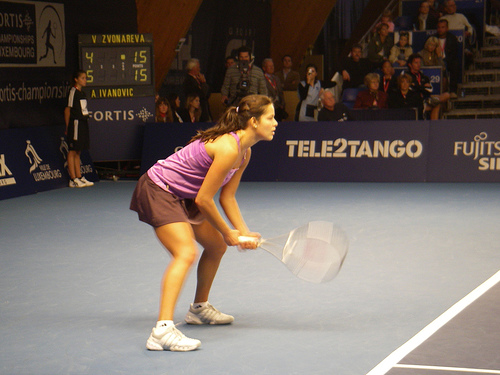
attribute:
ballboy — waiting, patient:
[61, 65, 96, 188]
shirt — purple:
[147, 133, 249, 193]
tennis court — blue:
[0, 185, 495, 370]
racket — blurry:
[254, 209, 365, 290]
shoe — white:
[142, 318, 204, 359]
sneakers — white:
[153, 276, 240, 372]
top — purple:
[143, 131, 248, 197]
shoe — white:
[134, 306, 258, 370]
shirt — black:
[391, 87, 421, 114]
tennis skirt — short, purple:
[124, 167, 223, 238]